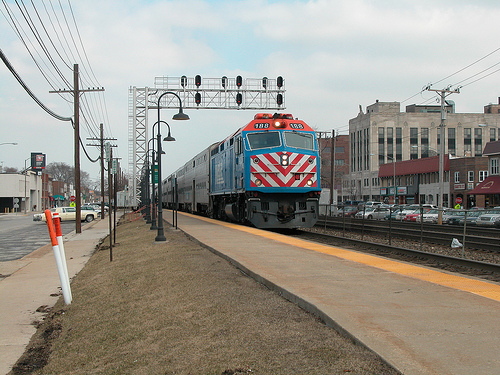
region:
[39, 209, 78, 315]
group of orange and white poles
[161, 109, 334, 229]
red and blue train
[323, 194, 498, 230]
group of parked cars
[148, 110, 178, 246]
light pole next to track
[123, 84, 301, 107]
lights that warn train is coming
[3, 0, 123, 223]
telephone lines and electrical lines on poles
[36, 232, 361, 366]
grassy area next to train track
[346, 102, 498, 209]
group of buildings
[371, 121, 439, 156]
building with lots of windows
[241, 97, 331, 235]
front of train on track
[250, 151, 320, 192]
the red and white front of the train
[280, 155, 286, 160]
the white bright headlight of the train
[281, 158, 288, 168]
the white bright headlight of the train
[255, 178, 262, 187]
the white bright headlight of the train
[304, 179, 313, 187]
the white bright headlight of the train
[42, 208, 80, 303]
the white and orange pole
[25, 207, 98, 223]
the tan long car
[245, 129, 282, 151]
the train window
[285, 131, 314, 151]
the train window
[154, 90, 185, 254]
street lamp next to train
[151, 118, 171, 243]
street lamp next to train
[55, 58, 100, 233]
electric pole next to tracks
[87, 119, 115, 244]
electric pole next to tracks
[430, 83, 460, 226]
electric pole next to tracks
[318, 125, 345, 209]
electric pole next to tracks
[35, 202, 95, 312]
poles in the ground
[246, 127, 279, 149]
window on the train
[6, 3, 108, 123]
wires on the telephone pole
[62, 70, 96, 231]
a telephone pole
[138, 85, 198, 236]
lamp posts next to the train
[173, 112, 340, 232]
a train on the train tracks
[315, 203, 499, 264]
a fence behind the train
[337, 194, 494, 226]
cars parked behind the fence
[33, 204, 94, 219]
a white car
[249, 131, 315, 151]
windows on the train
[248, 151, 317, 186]
the red metal striped front of a train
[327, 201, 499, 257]
a metal chain link fence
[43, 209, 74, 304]
a white and orange post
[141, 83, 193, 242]
a row of lights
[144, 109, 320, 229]
a long blue train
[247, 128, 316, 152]
the front windshield of a train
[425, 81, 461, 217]
a tall wooden power line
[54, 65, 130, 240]
a row of power lines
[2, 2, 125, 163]
long wires